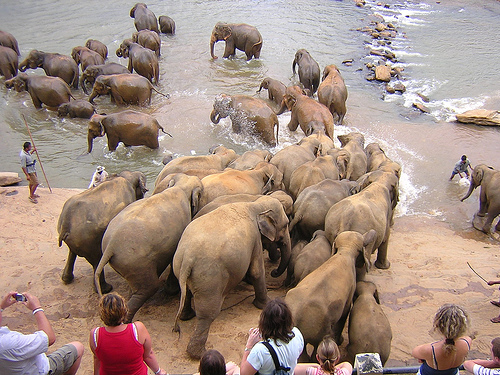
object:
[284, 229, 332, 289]
elephants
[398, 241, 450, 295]
sand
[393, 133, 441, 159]
water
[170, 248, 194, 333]
elephant tail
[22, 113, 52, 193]
stick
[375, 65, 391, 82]
rock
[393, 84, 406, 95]
rock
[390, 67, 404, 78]
rock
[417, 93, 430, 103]
rock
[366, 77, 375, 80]
rock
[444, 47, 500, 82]
water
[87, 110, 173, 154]
elephants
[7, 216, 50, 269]
sand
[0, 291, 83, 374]
man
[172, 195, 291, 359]
elephant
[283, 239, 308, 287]
elephant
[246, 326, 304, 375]
shirt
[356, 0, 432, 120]
big rocks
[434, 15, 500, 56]
water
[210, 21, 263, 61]
elephants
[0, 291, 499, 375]
crowd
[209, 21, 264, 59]
elephant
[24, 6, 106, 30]
water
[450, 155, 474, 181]
man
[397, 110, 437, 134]
water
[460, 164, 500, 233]
elephants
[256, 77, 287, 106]
elephant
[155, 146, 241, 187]
elephant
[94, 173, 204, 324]
elephant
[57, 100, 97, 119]
elephant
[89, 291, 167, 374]
woman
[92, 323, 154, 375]
red shirt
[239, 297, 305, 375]
woman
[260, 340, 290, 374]
bag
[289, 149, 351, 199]
elephants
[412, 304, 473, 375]
woman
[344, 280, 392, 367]
elephants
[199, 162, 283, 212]
elephants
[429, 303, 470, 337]
band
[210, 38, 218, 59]
trunk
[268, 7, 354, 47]
water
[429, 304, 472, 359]
hair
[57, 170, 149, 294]
elephants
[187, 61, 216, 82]
water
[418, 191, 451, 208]
water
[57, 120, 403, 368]
group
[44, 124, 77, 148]
water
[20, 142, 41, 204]
man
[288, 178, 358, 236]
elephants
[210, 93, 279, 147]
wet